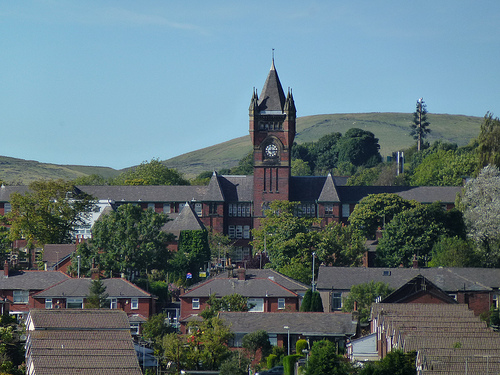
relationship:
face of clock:
[265, 144, 279, 157] [260, 135, 283, 166]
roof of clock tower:
[248, 46, 297, 116] [248, 46, 299, 258]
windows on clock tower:
[258, 120, 286, 132] [248, 46, 299, 258]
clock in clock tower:
[260, 135, 283, 166] [248, 46, 299, 258]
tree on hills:
[407, 95, 433, 152] [1, 111, 500, 188]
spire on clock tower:
[269, 46, 278, 72] [248, 46, 299, 258]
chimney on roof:
[236, 265, 248, 281] [180, 278, 299, 300]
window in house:
[189, 299, 202, 311] [178, 266, 299, 343]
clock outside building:
[260, 135, 283, 166] [206, 47, 341, 286]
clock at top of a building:
[260, 135, 283, 166] [206, 47, 341, 286]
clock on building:
[260, 135, 283, 166] [206, 47, 341, 286]